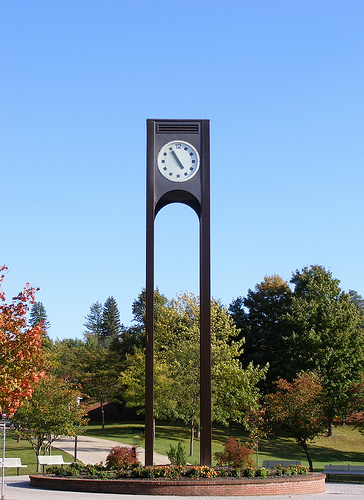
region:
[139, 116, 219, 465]
the clock tower is tall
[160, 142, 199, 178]
the clock is white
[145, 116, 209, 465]
the clock tower is black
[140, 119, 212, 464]
the clock tower has vents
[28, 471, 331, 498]
the planter is made of brick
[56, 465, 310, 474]
the flowers are in the planter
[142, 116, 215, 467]
the clock tower has an arch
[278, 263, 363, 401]
the tree is tall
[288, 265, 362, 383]
the tree is green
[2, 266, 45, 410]
the leaves are red and yellow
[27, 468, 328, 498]
circular brick wall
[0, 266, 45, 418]
red leaves on a tree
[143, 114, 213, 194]
large clock in a park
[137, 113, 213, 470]
clock on two tall brown poles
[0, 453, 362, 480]
four white benches in a park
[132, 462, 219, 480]
salmon colored flowers on a brick wall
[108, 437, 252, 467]
two red bushes near a brick wall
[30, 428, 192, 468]
paved pathway down a green hill in a park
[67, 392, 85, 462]
street light behind a tree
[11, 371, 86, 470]
short green tree obscuring a street light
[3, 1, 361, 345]
sky is beautiful, clear and blue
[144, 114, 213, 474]
very tall clock tower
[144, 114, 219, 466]
tall artistic clock tower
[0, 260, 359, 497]
trees are green and red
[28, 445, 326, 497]
planter full of plants below clock tower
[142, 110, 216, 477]
clock tower is metallic and dark brown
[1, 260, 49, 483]
tree is starting to lose it's leaves as they turn red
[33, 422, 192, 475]
cement walking path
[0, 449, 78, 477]
two white benches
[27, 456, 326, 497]
planter is built with bricks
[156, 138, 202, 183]
clock on the sign.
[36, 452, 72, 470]
White bench in the background.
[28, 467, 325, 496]
Circular brick planter.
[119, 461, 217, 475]
Orange flowers in the bed.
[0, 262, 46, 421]
Red leaves on the tree.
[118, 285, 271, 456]
Green tree in the background.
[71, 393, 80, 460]
Streetlight on the walkway.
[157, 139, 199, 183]
black hands on the clock.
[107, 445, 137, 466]
Bush in the background.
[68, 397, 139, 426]
House in the background.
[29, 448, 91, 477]
the bench is empty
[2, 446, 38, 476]
the bench is empty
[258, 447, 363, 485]
the bench is empty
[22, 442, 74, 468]
the bench is white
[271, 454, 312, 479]
the bench is white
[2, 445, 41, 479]
the bench is white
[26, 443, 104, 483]
the bench is white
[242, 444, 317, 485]
the bench is white